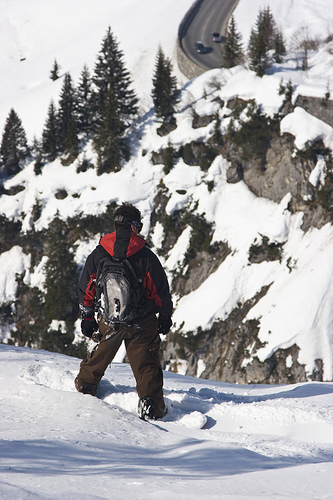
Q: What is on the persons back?
A: Back pack.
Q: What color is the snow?
A: White.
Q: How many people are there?
A: One.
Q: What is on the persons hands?
A: Gloves.